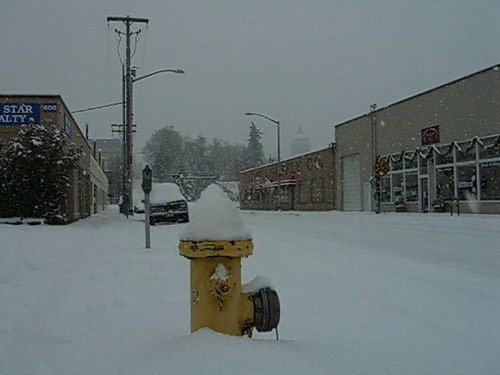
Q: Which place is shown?
A: It is a street.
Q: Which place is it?
A: It is a street.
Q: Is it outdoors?
A: Yes, it is outdoors.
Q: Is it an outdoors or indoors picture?
A: It is outdoors.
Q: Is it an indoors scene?
A: No, it is outdoors.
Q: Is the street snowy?
A: Yes, the street is snowy.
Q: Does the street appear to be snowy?
A: Yes, the street is snowy.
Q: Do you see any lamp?
A: Yes, there is a lamp.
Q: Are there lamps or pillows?
A: Yes, there is a lamp.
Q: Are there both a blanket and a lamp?
A: No, there is a lamp but no blankets.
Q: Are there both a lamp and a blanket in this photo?
A: No, there is a lamp but no blankets.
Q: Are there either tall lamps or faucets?
A: Yes, there is a tall lamp.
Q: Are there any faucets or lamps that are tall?
A: Yes, the lamp is tall.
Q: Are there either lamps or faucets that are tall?
A: Yes, the lamp is tall.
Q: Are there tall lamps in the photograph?
A: Yes, there is a tall lamp.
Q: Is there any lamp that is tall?
A: Yes, there is a lamp that is tall.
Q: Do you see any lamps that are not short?
A: Yes, there is a tall lamp.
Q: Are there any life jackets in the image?
A: No, there are no life jackets.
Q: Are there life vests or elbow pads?
A: No, there are no life vests or elbow pads.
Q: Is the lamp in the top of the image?
A: Yes, the lamp is in the top of the image.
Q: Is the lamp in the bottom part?
A: No, the lamp is in the top of the image.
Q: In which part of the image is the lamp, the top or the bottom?
A: The lamp is in the top of the image.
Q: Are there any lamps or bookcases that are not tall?
A: No, there is a lamp but it is tall.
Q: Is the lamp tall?
A: Yes, the lamp is tall.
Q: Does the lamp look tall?
A: Yes, the lamp is tall.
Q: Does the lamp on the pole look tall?
A: Yes, the lamp is tall.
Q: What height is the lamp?
A: The lamp is tall.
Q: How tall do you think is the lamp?
A: The lamp is tall.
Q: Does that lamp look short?
A: No, the lamp is tall.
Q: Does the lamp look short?
A: No, the lamp is tall.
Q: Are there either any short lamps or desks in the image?
A: No, there is a lamp but it is tall.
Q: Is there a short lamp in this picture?
A: No, there is a lamp but it is tall.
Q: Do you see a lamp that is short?
A: No, there is a lamp but it is tall.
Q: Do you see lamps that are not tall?
A: No, there is a lamp but it is tall.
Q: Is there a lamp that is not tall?
A: No, there is a lamp but it is tall.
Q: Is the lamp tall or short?
A: The lamp is tall.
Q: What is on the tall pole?
A: The lamp is on the pole.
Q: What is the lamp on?
A: The lamp is on the pole.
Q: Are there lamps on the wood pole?
A: Yes, there is a lamp on the pole.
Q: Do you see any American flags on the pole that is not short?
A: No, there is a lamp on the pole.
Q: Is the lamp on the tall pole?
A: Yes, the lamp is on the pole.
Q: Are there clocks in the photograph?
A: No, there are no clocks.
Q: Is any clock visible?
A: No, there are no clocks.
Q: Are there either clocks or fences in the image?
A: No, there are no clocks or fences.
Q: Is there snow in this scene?
A: Yes, there is snow.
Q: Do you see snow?
A: Yes, there is snow.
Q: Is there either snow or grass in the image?
A: Yes, there is snow.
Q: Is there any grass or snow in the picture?
A: Yes, there is snow.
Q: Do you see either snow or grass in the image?
A: Yes, there is snow.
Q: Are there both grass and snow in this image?
A: No, there is snow but no grass.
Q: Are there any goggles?
A: No, there are no goggles.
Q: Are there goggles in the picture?
A: No, there are no goggles.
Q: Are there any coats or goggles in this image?
A: No, there are no goggles or coats.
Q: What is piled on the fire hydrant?
A: The snow is piled on the fire hydrant.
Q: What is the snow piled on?
A: The snow is piled on the fire hydrant.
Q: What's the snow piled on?
A: The snow is piled on the fire hydrant.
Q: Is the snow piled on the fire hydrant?
A: Yes, the snow is piled on the fire hydrant.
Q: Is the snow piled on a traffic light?
A: No, the snow is piled on the fire hydrant.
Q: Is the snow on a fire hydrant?
A: Yes, the snow is on a fire hydrant.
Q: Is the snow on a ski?
A: No, the snow is on a fire hydrant.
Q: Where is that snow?
A: The snow is in the street.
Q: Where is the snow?
A: The snow is in the street.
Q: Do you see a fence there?
A: No, there are no fences.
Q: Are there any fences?
A: No, there are no fences.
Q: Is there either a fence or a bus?
A: No, there are no fences or buses.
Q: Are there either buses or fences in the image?
A: No, there are no fences or buses.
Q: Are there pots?
A: No, there are no pots.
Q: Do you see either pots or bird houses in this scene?
A: No, there are no pots or bird houses.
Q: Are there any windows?
A: Yes, there are windows.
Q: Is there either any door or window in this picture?
A: Yes, there are windows.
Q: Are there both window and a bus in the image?
A: No, there are windows but no buses.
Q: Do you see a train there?
A: No, there are no trains.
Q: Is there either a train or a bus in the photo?
A: No, there are no trains or buses.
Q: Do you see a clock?
A: No, there are no clocks.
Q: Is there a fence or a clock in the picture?
A: No, there are no clocks or fences.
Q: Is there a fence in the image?
A: No, there are no fences.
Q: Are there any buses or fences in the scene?
A: No, there are no fences or buses.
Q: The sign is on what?
A: The sign is on the building.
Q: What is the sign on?
A: The sign is on the building.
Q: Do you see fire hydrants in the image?
A: Yes, there is a fire hydrant.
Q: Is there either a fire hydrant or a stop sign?
A: Yes, there is a fire hydrant.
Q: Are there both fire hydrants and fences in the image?
A: No, there is a fire hydrant but no fences.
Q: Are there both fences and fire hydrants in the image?
A: No, there is a fire hydrant but no fences.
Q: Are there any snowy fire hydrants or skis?
A: Yes, there is a snowy fire hydrant.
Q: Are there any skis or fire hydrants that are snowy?
A: Yes, the fire hydrant is snowy.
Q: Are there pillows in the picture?
A: No, there are no pillows.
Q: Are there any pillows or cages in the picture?
A: No, there are no pillows or cages.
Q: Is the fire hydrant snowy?
A: Yes, the fire hydrant is snowy.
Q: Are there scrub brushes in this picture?
A: No, there are no scrub brushes.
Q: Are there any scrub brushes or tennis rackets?
A: No, there are no scrub brushes or tennis rackets.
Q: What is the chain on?
A: The chain is on the hydrant.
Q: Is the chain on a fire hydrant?
A: Yes, the chain is on a fire hydrant.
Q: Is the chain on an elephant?
A: No, the chain is on a fire hydrant.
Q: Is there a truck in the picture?
A: Yes, there is a truck.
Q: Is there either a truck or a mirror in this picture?
A: Yes, there is a truck.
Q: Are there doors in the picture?
A: Yes, there is a door.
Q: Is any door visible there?
A: Yes, there is a door.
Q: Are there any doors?
A: Yes, there is a door.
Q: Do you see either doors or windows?
A: Yes, there is a door.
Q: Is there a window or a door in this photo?
A: Yes, there is a door.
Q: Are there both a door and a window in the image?
A: Yes, there are both a door and a window.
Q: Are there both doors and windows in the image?
A: Yes, there are both a door and a window.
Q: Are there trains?
A: No, there are no trains.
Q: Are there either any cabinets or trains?
A: No, there are no trains or cabinets.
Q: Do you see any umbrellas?
A: No, there are no umbrellas.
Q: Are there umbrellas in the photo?
A: No, there are no umbrellas.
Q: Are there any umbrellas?
A: No, there are no umbrellas.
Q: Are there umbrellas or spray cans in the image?
A: No, there are no umbrellas or spray cans.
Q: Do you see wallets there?
A: No, there are no wallets.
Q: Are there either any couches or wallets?
A: No, there are no wallets or couches.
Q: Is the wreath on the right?
A: Yes, the wreath is on the right of the image.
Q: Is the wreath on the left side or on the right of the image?
A: The wreath is on the right of the image.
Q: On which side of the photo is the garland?
A: The garland is on the right of the image.